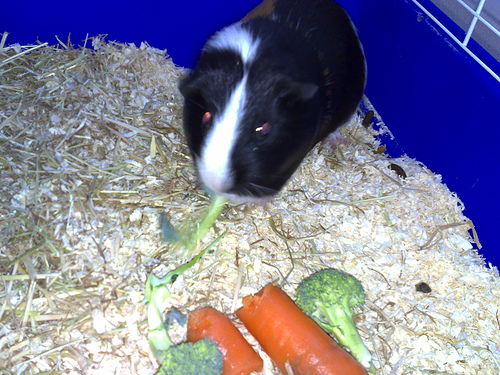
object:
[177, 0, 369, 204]
animal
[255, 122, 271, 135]
eye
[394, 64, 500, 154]
blue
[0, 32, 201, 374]
hay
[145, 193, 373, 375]
vegetable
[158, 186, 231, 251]
greens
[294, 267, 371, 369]
greens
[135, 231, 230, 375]
greens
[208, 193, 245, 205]
mouth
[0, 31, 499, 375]
wood chips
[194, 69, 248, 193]
stripe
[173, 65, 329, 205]
head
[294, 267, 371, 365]
broccoli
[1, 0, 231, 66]
wall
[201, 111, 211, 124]
eye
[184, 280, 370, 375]
carrots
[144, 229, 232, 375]
broccoli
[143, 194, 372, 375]
dinner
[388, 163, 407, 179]
poop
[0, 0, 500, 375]
cage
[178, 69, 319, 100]
ears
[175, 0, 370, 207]
guinea pig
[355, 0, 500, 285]
cage wall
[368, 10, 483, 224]
container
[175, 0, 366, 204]
gerbil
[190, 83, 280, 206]
face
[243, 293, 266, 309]
bite marks